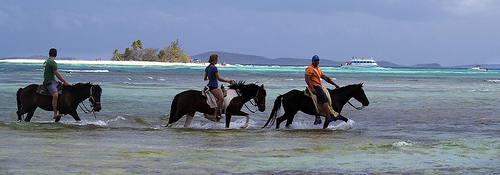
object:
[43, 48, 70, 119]
man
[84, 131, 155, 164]
water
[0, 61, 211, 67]
shore line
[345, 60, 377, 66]
boat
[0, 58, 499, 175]
ocean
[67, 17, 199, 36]
partially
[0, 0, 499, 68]
sky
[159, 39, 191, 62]
trees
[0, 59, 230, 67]
beach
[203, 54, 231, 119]
woman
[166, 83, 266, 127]
horse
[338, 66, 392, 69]
waves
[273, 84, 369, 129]
horses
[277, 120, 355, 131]
shallow water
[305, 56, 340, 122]
people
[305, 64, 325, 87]
orange shirt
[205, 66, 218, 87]
blue shirt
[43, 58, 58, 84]
green shirt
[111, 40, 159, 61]
green bush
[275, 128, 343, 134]
in water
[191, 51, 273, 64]
mountains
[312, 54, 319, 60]
baseball cap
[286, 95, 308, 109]
black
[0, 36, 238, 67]
small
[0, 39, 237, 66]
island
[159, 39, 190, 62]
range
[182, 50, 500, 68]
distance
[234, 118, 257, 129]
white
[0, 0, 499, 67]
back ground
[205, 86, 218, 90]
short shorts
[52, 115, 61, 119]
sandals